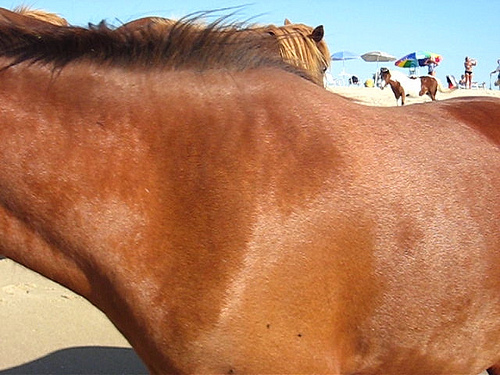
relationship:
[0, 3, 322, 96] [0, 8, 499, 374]
mane on flank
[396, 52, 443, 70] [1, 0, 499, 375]
umbrella on beach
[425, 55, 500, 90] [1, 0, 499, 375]
people on beach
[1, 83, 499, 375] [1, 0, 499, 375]
beach at beach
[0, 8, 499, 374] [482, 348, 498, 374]
flank has a flank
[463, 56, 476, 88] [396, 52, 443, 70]
woman near umbrella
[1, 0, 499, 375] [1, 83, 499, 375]
beach has beach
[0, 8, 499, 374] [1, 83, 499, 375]
flank on beach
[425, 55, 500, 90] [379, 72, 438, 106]
people near horse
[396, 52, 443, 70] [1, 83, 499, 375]
umbrella on beach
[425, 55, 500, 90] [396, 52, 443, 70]
people near umbrella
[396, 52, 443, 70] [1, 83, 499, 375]
umbrella in beach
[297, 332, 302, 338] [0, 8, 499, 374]
black mark on flank